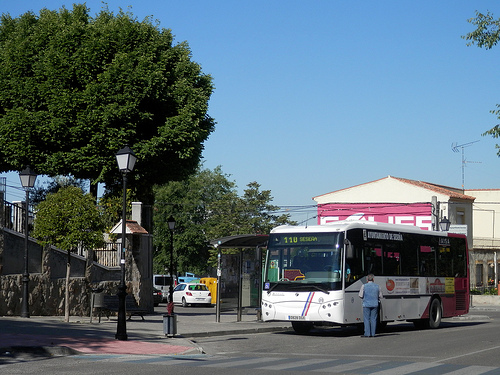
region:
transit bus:
[271, 201, 469, 335]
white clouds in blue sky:
[209, 20, 251, 67]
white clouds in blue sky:
[217, 54, 255, 98]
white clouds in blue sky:
[301, 32, 333, 87]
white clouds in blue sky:
[382, 49, 412, 90]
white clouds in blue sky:
[351, 71, 379, 101]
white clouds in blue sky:
[289, 114, 322, 154]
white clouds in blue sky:
[279, 28, 318, 85]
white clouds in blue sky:
[241, 110, 306, 156]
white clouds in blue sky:
[299, 58, 341, 109]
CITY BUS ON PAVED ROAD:
[247, 186, 498, 320]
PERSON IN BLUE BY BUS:
[358, 265, 393, 331]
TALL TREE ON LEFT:
[3, 47, 215, 176]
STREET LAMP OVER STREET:
[115, 133, 154, 355]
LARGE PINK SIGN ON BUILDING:
[314, 200, 446, 259]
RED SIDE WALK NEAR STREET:
[88, 314, 198, 369]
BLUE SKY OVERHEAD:
[232, 40, 384, 165]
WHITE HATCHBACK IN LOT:
[159, 263, 215, 310]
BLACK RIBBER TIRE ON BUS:
[417, 292, 437, 331]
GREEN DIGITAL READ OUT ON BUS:
[272, 236, 328, 245]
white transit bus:
[264, 215, 476, 339]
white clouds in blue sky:
[197, 15, 257, 53]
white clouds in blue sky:
[235, 52, 267, 87]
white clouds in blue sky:
[225, 92, 269, 162]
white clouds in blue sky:
[248, 125, 320, 159]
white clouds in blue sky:
[308, 103, 365, 145]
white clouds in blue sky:
[352, 96, 417, 140]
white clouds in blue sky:
[254, 42, 372, 114]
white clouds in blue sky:
[357, 61, 429, 115]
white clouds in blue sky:
[275, 16, 332, 66]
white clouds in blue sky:
[219, 36, 270, 98]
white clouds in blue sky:
[222, 78, 262, 113]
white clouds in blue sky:
[249, 128, 272, 158]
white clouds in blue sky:
[264, 144, 296, 154]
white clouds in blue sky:
[273, 28, 302, 73]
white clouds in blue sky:
[315, 140, 346, 155]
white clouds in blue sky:
[315, 80, 394, 133]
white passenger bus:
[249, 192, 461, 336]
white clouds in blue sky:
[262, 25, 292, 82]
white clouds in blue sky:
[302, 62, 377, 117]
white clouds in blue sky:
[332, 100, 379, 151]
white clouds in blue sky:
[412, 115, 435, 145]